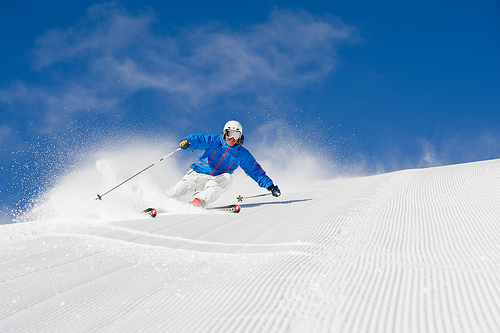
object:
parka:
[178, 134, 273, 188]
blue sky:
[0, 0, 494, 224]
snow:
[0, 148, 500, 329]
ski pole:
[236, 192, 270, 198]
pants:
[153, 170, 229, 204]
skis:
[142, 207, 156, 218]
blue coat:
[141, 119, 280, 217]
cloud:
[0, 0, 492, 224]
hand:
[178, 139, 189, 147]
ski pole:
[93, 147, 187, 203]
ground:
[0, 157, 493, 330]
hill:
[0, 157, 500, 330]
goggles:
[221, 129, 241, 138]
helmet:
[223, 119, 243, 142]